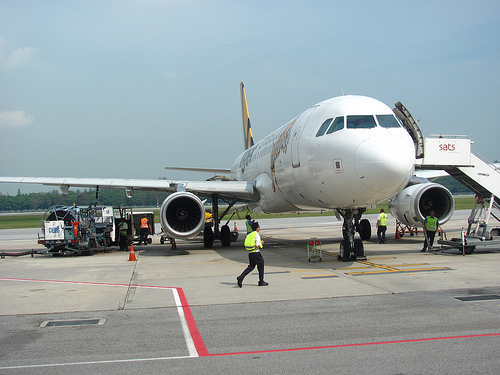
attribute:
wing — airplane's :
[239, 80, 256, 151]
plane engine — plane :
[156, 187, 223, 256]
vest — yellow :
[241, 231, 262, 259]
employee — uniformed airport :
[415, 211, 438, 253]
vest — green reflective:
[242, 230, 260, 252]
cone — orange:
[126, 243, 141, 265]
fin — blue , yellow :
[239, 80, 254, 150]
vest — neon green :
[243, 230, 263, 254]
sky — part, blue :
[2, 5, 499, 167]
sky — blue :
[95, 52, 183, 114]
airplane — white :
[0, 93, 499, 269]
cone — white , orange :
[124, 243, 137, 262]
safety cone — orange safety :
[127, 244, 140, 265]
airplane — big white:
[0, 85, 499, 256]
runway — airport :
[0, 217, 500, 374]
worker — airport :
[205, 219, 320, 306]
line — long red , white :
[159, 315, 209, 366]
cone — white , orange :
[116, 228, 159, 262]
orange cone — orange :
[86, 245, 150, 278]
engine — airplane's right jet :
[154, 185, 207, 247]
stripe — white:
[119, 248, 136, 258]